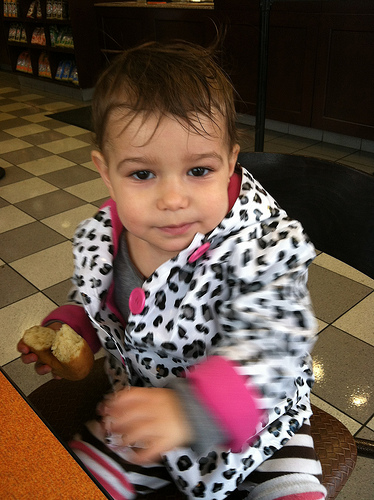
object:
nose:
[156, 175, 189, 212]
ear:
[91, 150, 116, 202]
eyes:
[125, 166, 214, 182]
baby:
[17, 42, 329, 500]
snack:
[39, 58, 45, 75]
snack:
[48, 30, 56, 43]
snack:
[30, 32, 38, 44]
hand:
[97, 386, 194, 463]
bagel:
[20, 322, 95, 381]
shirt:
[111, 227, 145, 325]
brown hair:
[88, 24, 248, 151]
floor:
[1, 74, 371, 496]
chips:
[56, 65, 69, 81]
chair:
[26, 355, 358, 500]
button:
[128, 287, 146, 315]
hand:
[16, 322, 63, 377]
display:
[2, 2, 94, 93]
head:
[89, 45, 241, 251]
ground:
[5, 114, 70, 265]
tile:
[27, 159, 56, 180]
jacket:
[40, 161, 314, 500]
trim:
[201, 358, 227, 403]